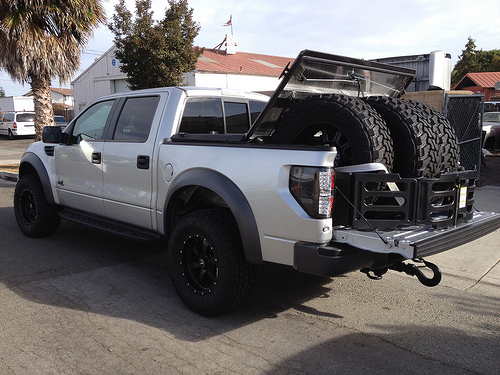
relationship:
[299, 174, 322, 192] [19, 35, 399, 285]
light of truck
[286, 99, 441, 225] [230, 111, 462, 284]
tire on back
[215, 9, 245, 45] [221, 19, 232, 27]
flag on flag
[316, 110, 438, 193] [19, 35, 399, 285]
wheel in photo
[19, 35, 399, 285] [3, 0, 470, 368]
truck in photo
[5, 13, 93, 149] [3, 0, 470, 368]
tree in photo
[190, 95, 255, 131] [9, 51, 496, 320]
window on truck